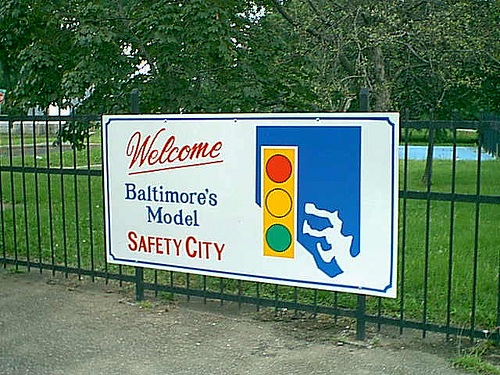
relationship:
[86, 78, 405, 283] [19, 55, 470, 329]
sign on fence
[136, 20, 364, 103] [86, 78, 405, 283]
tree behind sign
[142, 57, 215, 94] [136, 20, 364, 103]
leave on tree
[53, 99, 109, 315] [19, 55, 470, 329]
bar on fence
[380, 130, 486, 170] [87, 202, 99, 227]
pond next to grass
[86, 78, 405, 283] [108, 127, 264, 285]
sign has word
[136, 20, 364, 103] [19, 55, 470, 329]
tree behind fence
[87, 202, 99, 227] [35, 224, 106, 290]
grass on ground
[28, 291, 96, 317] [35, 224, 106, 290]
cement on ground